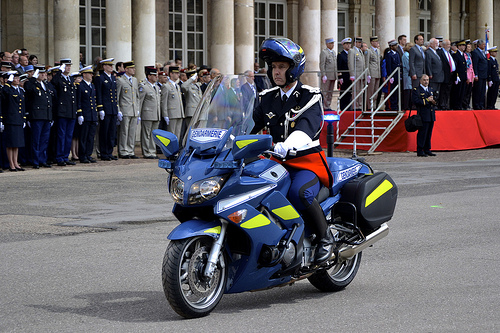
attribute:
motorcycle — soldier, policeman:
[158, 32, 401, 315]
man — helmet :
[261, 36, 308, 73]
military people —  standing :
[0, 43, 211, 167]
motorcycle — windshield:
[184, 75, 263, 133]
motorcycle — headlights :
[160, 174, 223, 204]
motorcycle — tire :
[160, 235, 240, 319]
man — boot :
[301, 199, 338, 241]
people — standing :
[325, 30, 483, 120]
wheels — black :
[151, 234, 231, 321]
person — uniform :
[233, 32, 339, 277]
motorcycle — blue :
[131, 69, 402, 325]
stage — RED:
[332, 109, 484, 150]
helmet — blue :
[257, 28, 308, 72]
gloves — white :
[273, 126, 308, 155]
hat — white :
[336, 35, 354, 46]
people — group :
[329, 29, 481, 101]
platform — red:
[335, 102, 484, 153]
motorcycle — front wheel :
[147, 230, 231, 320]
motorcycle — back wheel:
[304, 224, 369, 292]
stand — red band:
[332, 104, 484, 148]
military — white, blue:
[4, 47, 119, 163]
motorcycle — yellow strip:
[205, 170, 390, 240]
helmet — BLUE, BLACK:
[258, 31, 307, 87]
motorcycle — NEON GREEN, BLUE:
[150, 70, 400, 318]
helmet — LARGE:
[257, 31, 310, 81]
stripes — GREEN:
[198, 175, 397, 235]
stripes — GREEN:
[235, 134, 264, 148]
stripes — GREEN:
[153, 130, 171, 146]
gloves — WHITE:
[270, 126, 314, 160]